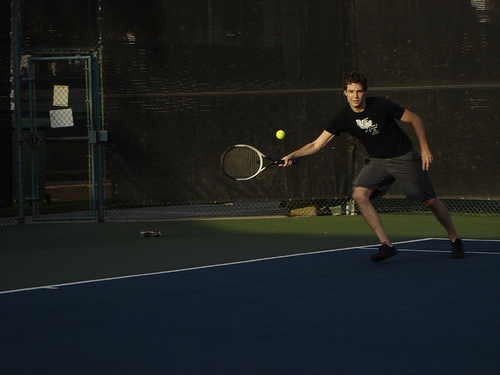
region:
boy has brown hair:
[338, 81, 378, 94]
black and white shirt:
[330, 88, 413, 179]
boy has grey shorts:
[355, 145, 430, 207]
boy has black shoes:
[378, 224, 459, 266]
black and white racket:
[171, 119, 302, 219]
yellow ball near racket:
[259, 128, 295, 145]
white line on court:
[51, 216, 341, 295]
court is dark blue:
[191, 256, 347, 343]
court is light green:
[178, 219, 295, 248]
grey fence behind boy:
[188, 84, 335, 216]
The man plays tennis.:
[216, 74, 466, 263]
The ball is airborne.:
[271, 128, 288, 142]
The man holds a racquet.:
[216, 142, 296, 184]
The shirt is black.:
[373, 138, 400, 153]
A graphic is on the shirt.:
[354, 117, 377, 136]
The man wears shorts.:
[356, 163, 435, 190]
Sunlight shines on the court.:
[218, 220, 357, 234]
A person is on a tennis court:
[11, 37, 473, 369]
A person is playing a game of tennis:
[28, 20, 441, 306]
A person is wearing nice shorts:
[36, 25, 491, 366]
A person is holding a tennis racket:
[65, 12, 480, 363]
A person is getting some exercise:
[40, 35, 478, 370]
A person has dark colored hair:
[57, 30, 469, 346]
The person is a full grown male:
[68, 37, 471, 357]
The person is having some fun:
[40, 25, 476, 348]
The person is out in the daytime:
[67, 23, 467, 358]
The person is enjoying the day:
[52, 32, 473, 342]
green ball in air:
[264, 122, 295, 144]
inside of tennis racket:
[233, 152, 250, 172]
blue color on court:
[230, 282, 297, 351]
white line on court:
[223, 256, 238, 271]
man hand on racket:
[276, 152, 297, 176]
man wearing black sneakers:
[351, 232, 413, 271]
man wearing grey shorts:
[408, 160, 420, 189]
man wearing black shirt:
[375, 135, 394, 150]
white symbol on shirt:
[351, 117, 375, 127]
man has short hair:
[347, 72, 357, 80]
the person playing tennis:
[194, 67, 474, 266]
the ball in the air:
[270, 121, 292, 143]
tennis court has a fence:
[4, 34, 491, 374]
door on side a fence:
[8, 48, 193, 209]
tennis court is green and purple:
[4, 207, 493, 374]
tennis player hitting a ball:
[203, 64, 475, 279]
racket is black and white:
[214, 136, 301, 185]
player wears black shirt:
[265, 67, 476, 270]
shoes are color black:
[369, 232, 469, 266]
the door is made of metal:
[4, 45, 121, 234]